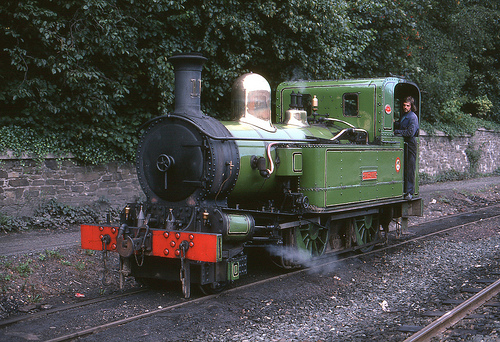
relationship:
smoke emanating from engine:
[256, 233, 349, 283] [78, 51, 423, 297]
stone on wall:
[11, 179, 117, 210] [3, 164, 142, 219]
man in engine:
[391, 98, 422, 200] [78, 51, 423, 297]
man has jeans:
[391, 98, 422, 200] [400, 136, 420, 205]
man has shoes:
[391, 98, 422, 200] [406, 192, 415, 201]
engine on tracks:
[78, 51, 423, 297] [28, 197, 404, 323]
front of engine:
[128, 100, 225, 277] [78, 51, 423, 297]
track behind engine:
[428, 182, 493, 246] [78, 51, 423, 297]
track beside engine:
[415, 260, 492, 340] [78, 51, 423, 297]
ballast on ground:
[269, 293, 373, 333] [157, 231, 466, 340]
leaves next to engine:
[67, 19, 217, 139] [78, 51, 423, 297]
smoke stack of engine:
[167, 51, 208, 115] [78, 51, 423, 297]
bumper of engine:
[70, 220, 224, 271] [78, 51, 423, 297]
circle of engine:
[135, 116, 204, 202] [78, 51, 423, 297]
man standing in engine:
[391, 98, 422, 200] [78, 51, 423, 297]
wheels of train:
[285, 227, 393, 263] [79, 65, 435, 293]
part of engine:
[234, 69, 283, 133] [78, 51, 423, 297]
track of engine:
[415, 260, 492, 340] [78, 51, 423, 297]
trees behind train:
[69, 52, 441, 302] [3, 3, 493, 163]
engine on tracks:
[78, 51, 423, 297] [26, 248, 373, 328]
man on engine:
[391, 98, 422, 200] [78, 51, 423, 297]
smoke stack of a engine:
[167, 51, 208, 115] [78, 51, 423, 297]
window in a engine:
[341, 90, 361, 114] [78, 51, 423, 297]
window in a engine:
[291, 88, 314, 110] [78, 51, 423, 297]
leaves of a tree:
[16, 19, 69, 63] [3, 2, 365, 149]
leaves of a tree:
[97, 7, 142, 59] [3, 2, 365, 149]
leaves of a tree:
[201, 12, 259, 53] [3, 2, 365, 149]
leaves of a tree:
[282, 10, 339, 45] [3, 2, 365, 149]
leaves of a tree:
[392, 24, 427, 48] [368, 0, 476, 132]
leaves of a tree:
[433, 38, 461, 66] [368, 0, 476, 132]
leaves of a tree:
[414, 66, 442, 94] [368, 0, 476, 132]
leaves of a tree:
[438, 80, 458, 103] [368, 0, 476, 132]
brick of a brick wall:
[2, 171, 28, 185] [0, 150, 144, 232]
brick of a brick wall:
[24, 187, 52, 197] [0, 150, 144, 232]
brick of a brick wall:
[70, 183, 95, 192] [0, 150, 144, 232]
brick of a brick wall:
[92, 169, 131, 179] [0, 150, 144, 232]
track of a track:
[434, 286, 481, 323] [415, 260, 492, 340]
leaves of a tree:
[284, 1, 307, 20] [262, 0, 382, 82]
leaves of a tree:
[317, 11, 345, 29] [262, 0, 382, 82]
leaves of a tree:
[324, 42, 348, 58] [262, 0, 382, 82]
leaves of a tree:
[355, 27, 380, 42] [262, 0, 382, 82]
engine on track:
[78, 51, 423, 297] [0, 268, 312, 340]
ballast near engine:
[269, 293, 373, 333] [78, 51, 423, 297]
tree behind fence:
[7, 3, 138, 123] [1, 127, 499, 233]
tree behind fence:
[145, 0, 262, 84] [1, 127, 499, 233]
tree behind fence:
[271, 2, 375, 77] [1, 127, 499, 233]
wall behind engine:
[2, 120, 499, 235] [78, 51, 423, 297]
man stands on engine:
[391, 98, 422, 200] [78, 51, 423, 297]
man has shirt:
[391, 98, 422, 200] [397, 110, 420, 138]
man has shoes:
[391, 98, 422, 200] [404, 192, 415, 200]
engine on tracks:
[78, 51, 423, 297] [0, 197, 498, 339]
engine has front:
[78, 51, 423, 297] [136, 49, 241, 239]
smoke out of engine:
[256, 233, 349, 283] [78, 51, 423, 297]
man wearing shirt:
[391, 98, 422, 200] [397, 110, 420, 138]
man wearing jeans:
[391, 98, 422, 200] [400, 136, 420, 205]